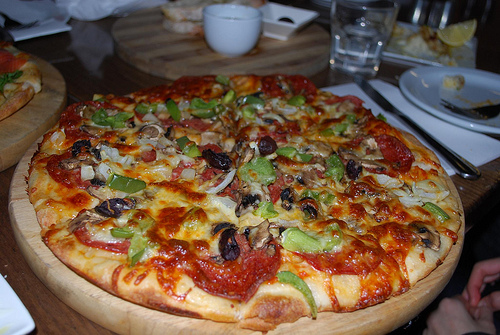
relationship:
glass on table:
[328, 3, 400, 78] [0, 3, 499, 335]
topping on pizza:
[219, 229, 238, 261] [27, 77, 464, 334]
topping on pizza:
[110, 222, 133, 239] [27, 77, 464, 334]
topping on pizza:
[375, 135, 413, 170] [27, 77, 464, 334]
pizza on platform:
[27, 77, 464, 334] [6, 122, 463, 335]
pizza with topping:
[27, 77, 464, 334] [219, 229, 238, 261]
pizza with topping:
[27, 77, 464, 334] [110, 222, 133, 239]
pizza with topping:
[27, 77, 464, 334] [375, 135, 413, 170]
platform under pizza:
[6, 122, 463, 335] [27, 77, 464, 334]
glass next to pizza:
[328, 3, 400, 78] [27, 77, 464, 334]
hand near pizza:
[422, 298, 495, 333] [27, 77, 464, 334]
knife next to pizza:
[354, 75, 482, 180] [27, 77, 464, 334]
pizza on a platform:
[27, 77, 464, 334] [6, 122, 463, 335]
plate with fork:
[399, 67, 499, 135] [444, 100, 500, 118]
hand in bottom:
[422, 298, 495, 333] [0, 245, 497, 334]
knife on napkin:
[354, 75, 482, 180] [321, 79, 499, 177]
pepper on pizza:
[190, 97, 214, 118] [27, 77, 464, 334]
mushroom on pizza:
[246, 218, 272, 251] [27, 77, 464, 334]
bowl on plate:
[202, 5, 262, 59] [113, 7, 330, 80]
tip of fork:
[443, 99, 455, 112] [444, 100, 500, 118]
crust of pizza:
[29, 129, 310, 334] [27, 77, 464, 334]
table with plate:
[0, 3, 499, 335] [399, 67, 499, 135]